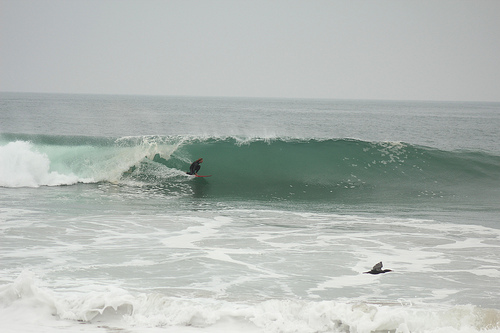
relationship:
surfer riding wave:
[181, 153, 207, 176] [1, 132, 500, 209]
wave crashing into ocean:
[1, 132, 500, 209] [1, 94, 500, 330]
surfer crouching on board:
[181, 153, 207, 176] [184, 173, 211, 178]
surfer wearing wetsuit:
[181, 153, 207, 176] [188, 160, 204, 175]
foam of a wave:
[0, 139, 94, 188] [1, 132, 500, 209]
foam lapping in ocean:
[1, 142, 95, 192] [1, 94, 500, 330]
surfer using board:
[181, 153, 207, 176] [184, 173, 211, 178]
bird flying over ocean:
[364, 260, 394, 279] [1, 94, 500, 330]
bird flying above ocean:
[364, 260, 394, 279] [1, 94, 500, 330]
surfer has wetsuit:
[181, 153, 207, 176] [188, 160, 204, 175]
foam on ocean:
[1, 142, 95, 192] [1, 94, 500, 330]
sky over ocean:
[3, 3, 499, 104] [1, 94, 500, 330]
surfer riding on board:
[181, 153, 207, 176] [184, 173, 211, 178]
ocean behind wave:
[1, 94, 500, 330] [1, 132, 500, 209]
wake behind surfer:
[142, 158, 193, 185] [181, 153, 207, 176]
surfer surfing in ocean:
[181, 153, 207, 176] [1, 94, 500, 330]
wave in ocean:
[1, 132, 500, 209] [1, 94, 500, 330]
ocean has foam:
[1, 94, 500, 330] [1, 142, 95, 192]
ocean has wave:
[1, 94, 500, 330] [1, 132, 500, 209]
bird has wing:
[364, 260, 394, 279] [372, 261, 385, 270]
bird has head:
[364, 260, 394, 279] [382, 266, 393, 273]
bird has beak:
[364, 260, 394, 279] [388, 268, 392, 273]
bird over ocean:
[364, 260, 394, 279] [1, 94, 500, 330]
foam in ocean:
[1, 142, 95, 192] [1, 94, 500, 330]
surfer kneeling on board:
[181, 153, 207, 176] [184, 173, 211, 178]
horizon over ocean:
[2, 69, 499, 102] [1, 94, 500, 330]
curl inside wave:
[122, 136, 183, 182] [1, 132, 500, 209]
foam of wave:
[0, 139, 94, 188] [1, 132, 500, 209]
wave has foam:
[1, 132, 500, 209] [0, 139, 94, 188]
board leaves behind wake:
[184, 173, 211, 178] [142, 158, 193, 185]